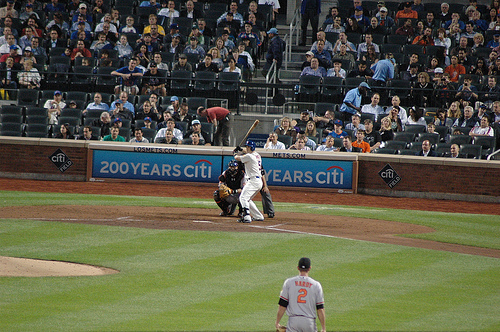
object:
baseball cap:
[298, 256, 311, 270]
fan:
[196, 105, 234, 148]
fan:
[156, 125, 185, 144]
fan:
[129, 129, 151, 144]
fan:
[75, 125, 102, 140]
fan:
[54, 122, 76, 139]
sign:
[220, 147, 355, 192]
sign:
[89, 144, 226, 185]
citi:
[380, 167, 396, 179]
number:
[296, 288, 308, 306]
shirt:
[278, 270, 326, 317]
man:
[339, 81, 371, 117]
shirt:
[338, 88, 362, 114]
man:
[363, 52, 398, 82]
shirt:
[368, 60, 396, 83]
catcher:
[214, 161, 251, 218]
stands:
[0, 51, 500, 163]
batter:
[225, 133, 269, 226]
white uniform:
[236, 150, 265, 222]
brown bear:
[323, 211, 430, 261]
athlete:
[274, 252, 329, 331]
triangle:
[46, 148, 75, 174]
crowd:
[1, 1, 491, 157]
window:
[86, 148, 225, 184]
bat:
[232, 118, 260, 156]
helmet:
[244, 139, 257, 153]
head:
[244, 141, 259, 154]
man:
[352, 127, 373, 151]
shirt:
[349, 140, 372, 152]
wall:
[0, 131, 500, 204]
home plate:
[192, 213, 212, 224]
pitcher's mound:
[1, 241, 135, 297]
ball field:
[0, 171, 499, 328]